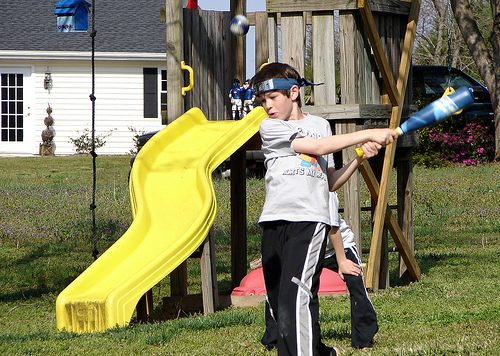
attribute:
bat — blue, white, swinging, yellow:
[355, 85, 474, 160]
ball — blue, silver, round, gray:
[228, 12, 252, 37]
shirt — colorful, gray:
[256, 112, 336, 227]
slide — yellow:
[52, 105, 271, 328]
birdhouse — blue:
[53, 1, 94, 34]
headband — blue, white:
[251, 76, 325, 94]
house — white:
[1, 1, 170, 159]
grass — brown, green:
[1, 156, 499, 356]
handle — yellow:
[353, 127, 404, 158]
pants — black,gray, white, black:
[260, 217, 331, 355]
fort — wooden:
[263, 1, 423, 293]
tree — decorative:
[39, 101, 59, 158]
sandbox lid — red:
[228, 261, 354, 307]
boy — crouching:
[250, 189, 380, 351]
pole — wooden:
[165, 2, 185, 131]